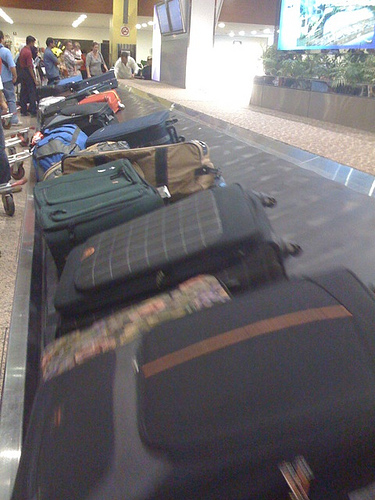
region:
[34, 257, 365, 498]
Black suitcase on a belt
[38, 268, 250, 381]
Floral suitcase on a belt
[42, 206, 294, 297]
Plaid suitcase on a belt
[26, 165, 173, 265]
Green suitcase on a belt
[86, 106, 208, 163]
Blue suitcase on a belt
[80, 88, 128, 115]
Orange suitcase on a belt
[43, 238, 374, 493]
Suitcases at baggage claim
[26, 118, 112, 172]
Blue duffle bag on a belt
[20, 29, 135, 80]
People waiting for their luggage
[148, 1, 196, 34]
Moniter in an airport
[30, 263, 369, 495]
a suitcase on an airport carousel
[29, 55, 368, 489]
a carousel at an airport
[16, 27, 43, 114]
a man waiting for luggage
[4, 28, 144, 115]
a group of people waiting for luggage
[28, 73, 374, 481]
a whole lot of suitcases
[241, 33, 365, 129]
a planter for appearance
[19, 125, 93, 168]
a blue bag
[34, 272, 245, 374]
a colorful suitcase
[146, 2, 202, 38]
monitors with flight information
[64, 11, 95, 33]
ceiling light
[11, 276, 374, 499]
Black suitcase on a conveyor belt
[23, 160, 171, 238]
Green suitcase on a conveyor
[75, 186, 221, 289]
Plaid front pocket on a suitcase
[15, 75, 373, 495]
Luggage on a moving conveyor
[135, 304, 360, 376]
Brown stripe on a suitcase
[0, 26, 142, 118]
People waiting for their luggage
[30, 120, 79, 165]
Blue duffel bag on a conveyor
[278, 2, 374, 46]
Monitor hanging over luggage conveyor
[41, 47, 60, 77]
Blue shirt on a man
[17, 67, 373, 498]
conveyor belt loaded with suitcases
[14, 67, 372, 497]
suitcases on conveyor belt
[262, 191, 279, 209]
a wheel of the suitcase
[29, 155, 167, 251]
a green suitcase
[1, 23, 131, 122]
people standing next to the conveyor belt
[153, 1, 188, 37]
a monitor on the wall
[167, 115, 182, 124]
a wheel of the suitcase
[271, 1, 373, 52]
a monitor on the wall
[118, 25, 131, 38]
a sign on the wall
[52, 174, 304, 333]
black suitcase with wheels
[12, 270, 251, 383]
a flower covered suitcase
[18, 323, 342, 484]
A piece of luggage.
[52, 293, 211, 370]
A piece of luggage.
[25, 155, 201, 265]
A piece of luggage.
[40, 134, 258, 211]
A piece of luggage.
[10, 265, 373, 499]
a piece of luggage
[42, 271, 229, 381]
a piece of luggage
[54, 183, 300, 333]
a piece of luggage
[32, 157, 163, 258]
a piece of luggage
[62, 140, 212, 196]
a piece of luggage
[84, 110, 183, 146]
a piece of luggage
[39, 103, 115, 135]
a piece of luggage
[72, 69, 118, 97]
a piece of luggage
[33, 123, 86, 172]
a piece of luggage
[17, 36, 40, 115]
man wearing a red shirt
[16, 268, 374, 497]
a piece of black luggage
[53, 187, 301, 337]
a piece of black luggage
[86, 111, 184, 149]
a piece of black luggage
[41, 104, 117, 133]
a piece of black luggage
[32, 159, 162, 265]
a piece of green luggage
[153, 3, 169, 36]
a wall mounted screen